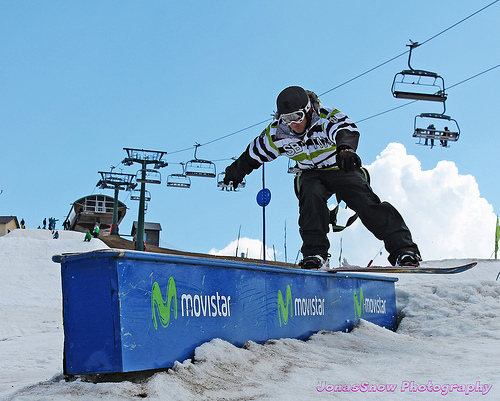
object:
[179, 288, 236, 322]
'movistar' logo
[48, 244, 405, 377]
ramp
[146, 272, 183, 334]
'movistar' logo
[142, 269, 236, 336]
movistar+logo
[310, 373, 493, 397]
photographer credit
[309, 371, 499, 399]
right hand corner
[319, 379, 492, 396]
jonassnowphotography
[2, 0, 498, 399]
photo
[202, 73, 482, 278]
dude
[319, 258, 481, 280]
snowboard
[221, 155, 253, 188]
gloves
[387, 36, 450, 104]
chair lift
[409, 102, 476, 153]
chair lift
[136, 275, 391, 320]
'movistar' 3 times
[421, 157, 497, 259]
cloud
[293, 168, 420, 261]
pants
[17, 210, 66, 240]
people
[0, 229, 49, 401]
slope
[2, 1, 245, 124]
sky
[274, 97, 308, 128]
goggles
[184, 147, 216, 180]
chair lifts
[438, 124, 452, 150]
person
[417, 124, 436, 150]
person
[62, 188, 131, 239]
terminal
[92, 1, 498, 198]
ski lift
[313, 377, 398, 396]
jonas snow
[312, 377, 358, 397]
jonas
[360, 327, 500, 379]
snow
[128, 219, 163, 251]
office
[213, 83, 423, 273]
snowboarder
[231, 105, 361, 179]
jacket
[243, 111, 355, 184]
stripes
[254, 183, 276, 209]
sign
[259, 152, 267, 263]
pole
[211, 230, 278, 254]
cloud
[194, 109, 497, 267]
bottom of sky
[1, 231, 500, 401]
top of hill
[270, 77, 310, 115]
hat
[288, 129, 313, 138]
chinstrap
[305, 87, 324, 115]
hood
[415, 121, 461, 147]
people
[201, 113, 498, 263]
two prominent clouds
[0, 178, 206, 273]
ski resort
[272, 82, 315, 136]
head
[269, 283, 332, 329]
movistar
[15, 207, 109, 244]
loading area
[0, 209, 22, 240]
ski lift building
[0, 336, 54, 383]
snow